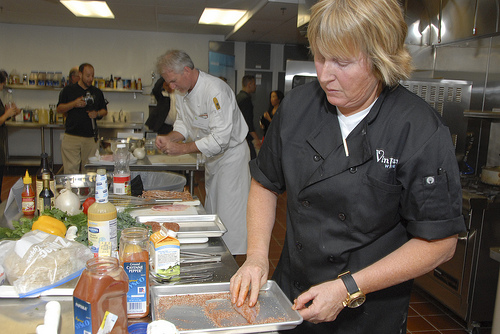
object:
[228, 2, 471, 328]
person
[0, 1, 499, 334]
kitchen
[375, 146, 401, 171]
logo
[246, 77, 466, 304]
shirt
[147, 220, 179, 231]
food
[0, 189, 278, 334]
table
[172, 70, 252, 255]
uniform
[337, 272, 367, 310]
watch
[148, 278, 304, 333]
tray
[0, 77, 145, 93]
shelf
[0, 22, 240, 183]
background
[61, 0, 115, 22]
light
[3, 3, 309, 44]
ceiling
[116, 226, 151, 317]
container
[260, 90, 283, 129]
woman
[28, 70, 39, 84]
item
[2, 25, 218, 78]
paint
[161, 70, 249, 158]
coat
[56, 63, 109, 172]
man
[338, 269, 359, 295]
strap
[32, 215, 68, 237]
pepper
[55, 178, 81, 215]
onion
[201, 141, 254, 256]
apron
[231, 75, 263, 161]
man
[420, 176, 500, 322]
oven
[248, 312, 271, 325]
meat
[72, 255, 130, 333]
carton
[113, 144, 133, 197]
oil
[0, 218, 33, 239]
greens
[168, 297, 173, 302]
spices